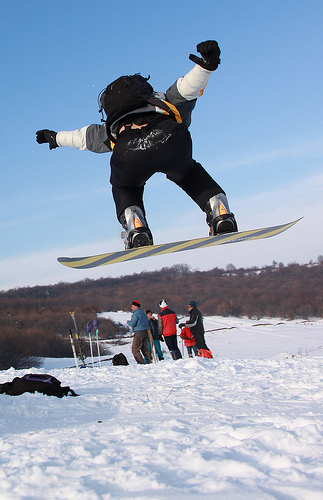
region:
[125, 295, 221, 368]
A group of people standing around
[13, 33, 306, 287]
The snow boarder flying through the air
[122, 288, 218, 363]
The people benathe the snowboarder in the foreground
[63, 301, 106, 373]
Skies and poles sticking out of the ground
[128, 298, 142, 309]
The red and black head cap on the man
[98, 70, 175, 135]
The black back pack on the snow boarder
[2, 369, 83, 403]
A bag laying on the ground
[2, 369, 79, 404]
A black bag with purple stripes in the snow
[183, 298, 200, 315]
A blue cap and orange googles on the person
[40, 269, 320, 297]
A dead wooded area behind the group of people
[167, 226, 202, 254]
the snowboard is yellow and gray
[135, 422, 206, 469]
the snow is clumpy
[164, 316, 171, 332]
the coat is red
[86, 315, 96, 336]
the gloves are purple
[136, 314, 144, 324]
the coat is blue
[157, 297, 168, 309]
the hat is white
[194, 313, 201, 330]
the coat is black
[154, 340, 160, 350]
the pants are teal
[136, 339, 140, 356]
the coats are brown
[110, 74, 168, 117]
the bag is on his back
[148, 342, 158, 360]
part of a stick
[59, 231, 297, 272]
A black and yellow snowboard in the air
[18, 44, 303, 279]
A man performing a snowboarding trick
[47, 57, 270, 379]
A group of snowboarders and skiers on a mountain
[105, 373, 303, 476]
Thick white snow is all over the ground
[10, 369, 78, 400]
A large black bag lies in the snow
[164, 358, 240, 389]
Small mounds of snow on the ground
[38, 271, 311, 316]
A great number of trees in the distance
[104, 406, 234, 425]
Tracks visible in the white snow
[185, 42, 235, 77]
Black gloves on the man's hands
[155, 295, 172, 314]
A white hat on the man in red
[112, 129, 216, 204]
Black trouser in the photo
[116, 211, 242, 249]
Black and gray shoe in the photo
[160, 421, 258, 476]
Ice covered surface in the photo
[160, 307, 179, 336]
Red and white jacket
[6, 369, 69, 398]
A black bag in the photo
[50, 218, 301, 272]
A skate board in the photo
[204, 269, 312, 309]
Trees in the photo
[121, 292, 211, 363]
People standing on ice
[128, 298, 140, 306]
A black and red hat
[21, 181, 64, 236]
clouds in the sky